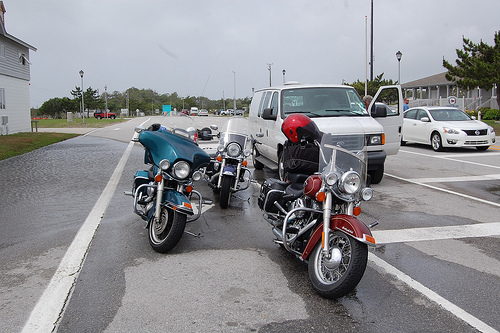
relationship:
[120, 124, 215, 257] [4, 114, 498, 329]
motorcycle parked on street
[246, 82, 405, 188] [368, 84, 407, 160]
van has a door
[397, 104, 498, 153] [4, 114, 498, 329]
car on street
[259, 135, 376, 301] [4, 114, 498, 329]
motorcycle parked on street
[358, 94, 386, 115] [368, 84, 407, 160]
man beside of door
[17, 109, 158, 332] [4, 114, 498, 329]
line on street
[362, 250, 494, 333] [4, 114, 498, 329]
line on street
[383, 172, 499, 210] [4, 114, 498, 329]
line on street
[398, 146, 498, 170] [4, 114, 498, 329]
line on street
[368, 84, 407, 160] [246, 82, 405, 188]
door on van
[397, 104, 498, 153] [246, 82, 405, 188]
car beside of van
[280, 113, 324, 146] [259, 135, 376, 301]
helmet on motorcycle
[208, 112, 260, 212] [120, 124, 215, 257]
motorcycle beside of motorcycle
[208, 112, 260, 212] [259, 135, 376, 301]
motorcycle beside of motorcycle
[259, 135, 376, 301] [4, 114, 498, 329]
motorcycle on street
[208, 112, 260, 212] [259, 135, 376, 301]
motorcycle behind motorcycle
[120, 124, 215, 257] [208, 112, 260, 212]
motorcycle behind motorcycle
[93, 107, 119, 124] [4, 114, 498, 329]
truck beside of street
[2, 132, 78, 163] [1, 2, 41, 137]
grass next to buildig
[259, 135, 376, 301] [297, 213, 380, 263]
motorcycle has a fender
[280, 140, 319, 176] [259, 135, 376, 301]
sleepig bag on motorcycle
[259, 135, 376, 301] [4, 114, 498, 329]
motorcycle sitting on street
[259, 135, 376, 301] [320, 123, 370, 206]
motorcycle has a wnidshield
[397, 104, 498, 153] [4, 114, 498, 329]
car parked on street